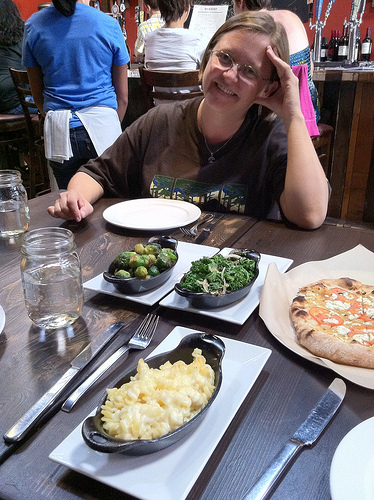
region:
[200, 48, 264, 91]
The lady is wearing glasses.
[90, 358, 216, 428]
Mac and cheese in the black pan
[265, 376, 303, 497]
A butter knife on the table.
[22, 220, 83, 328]
A glass of water on the table.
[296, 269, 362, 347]
Tomatoes on the pizza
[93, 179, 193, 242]
A white plate in front of a person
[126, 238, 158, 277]
green vegetable on the table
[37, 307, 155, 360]
A fork and knife next to each other.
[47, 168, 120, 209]
A person hand on the table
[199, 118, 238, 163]
the lady is wearing a necklace.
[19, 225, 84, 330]
glass jar half full of water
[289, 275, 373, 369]
pizza with tomatoes and cheese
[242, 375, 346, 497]
silver knofe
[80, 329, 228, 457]
bowl of pasta with cheese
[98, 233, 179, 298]
brussel sprouts in black bowl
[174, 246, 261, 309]
bowl of broccoli with onions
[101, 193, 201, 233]
empty white plate on the table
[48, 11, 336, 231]
woman wearing glasses smiling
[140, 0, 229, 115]
woman sitting on a chair looking at a menu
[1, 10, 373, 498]
woman in brown shirt sitting at table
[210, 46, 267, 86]
the woman is wearing glasses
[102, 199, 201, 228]
the plate is white in color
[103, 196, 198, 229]
the plate is made of ceramic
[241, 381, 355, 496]
the knife is made of metal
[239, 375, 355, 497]
the knife is made of steel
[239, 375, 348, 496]
the knife is shiny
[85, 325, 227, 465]
the bowl is black in color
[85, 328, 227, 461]
the bowl is on top of a dish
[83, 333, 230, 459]
the bowl is made of ceramic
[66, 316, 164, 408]
the fork is made of metal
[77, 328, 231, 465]
a bowl of pasta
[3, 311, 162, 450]
a fork and a knife on the table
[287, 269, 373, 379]
a pizza on the table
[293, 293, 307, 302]
a burnt part of the pizza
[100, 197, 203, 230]
a white plate on the table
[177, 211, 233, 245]
a fork and knife on the table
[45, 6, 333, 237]
a woman on the table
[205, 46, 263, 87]
eyeglasses the woman is wearing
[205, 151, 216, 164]
a pendant the woman is wearing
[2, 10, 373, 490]
a woman dining in the restaurant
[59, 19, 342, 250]
A woman sits at the table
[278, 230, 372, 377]
Pizza is on a paper towel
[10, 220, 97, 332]
A jar of water is half full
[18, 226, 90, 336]
A jar of water is half empty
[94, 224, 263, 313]
Vegetables are on two trays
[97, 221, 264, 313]
The trays are a black color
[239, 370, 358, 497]
A knife is on the table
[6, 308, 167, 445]
A fork and a knife is on the table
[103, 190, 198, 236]
A white plate is on the table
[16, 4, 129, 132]
The waiter is wearing a blue shirt